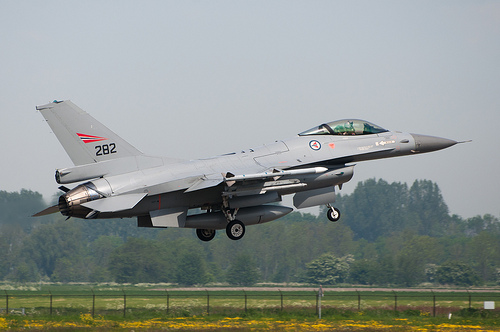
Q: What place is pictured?
A: It is an airport.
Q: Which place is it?
A: It is an airport.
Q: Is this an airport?
A: Yes, it is an airport.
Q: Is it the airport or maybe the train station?
A: It is the airport.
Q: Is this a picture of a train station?
A: No, the picture is showing an airport.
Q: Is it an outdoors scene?
A: Yes, it is outdoors.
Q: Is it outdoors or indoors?
A: It is outdoors.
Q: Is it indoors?
A: No, it is outdoors.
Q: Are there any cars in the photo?
A: No, there are no cars.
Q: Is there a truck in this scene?
A: No, there are no trucks.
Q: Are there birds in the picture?
A: No, there are no birds.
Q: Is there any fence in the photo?
A: Yes, there is a fence.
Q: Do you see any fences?
A: Yes, there is a fence.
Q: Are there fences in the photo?
A: Yes, there is a fence.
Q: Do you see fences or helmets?
A: Yes, there is a fence.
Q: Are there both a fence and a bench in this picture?
A: No, there is a fence but no benches.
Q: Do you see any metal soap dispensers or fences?
A: Yes, there is a metal fence.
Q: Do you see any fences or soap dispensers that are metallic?
A: Yes, the fence is metallic.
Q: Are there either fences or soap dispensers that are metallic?
A: Yes, the fence is metallic.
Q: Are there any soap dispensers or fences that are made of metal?
A: Yes, the fence is made of metal.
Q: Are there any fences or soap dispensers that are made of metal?
A: Yes, the fence is made of metal.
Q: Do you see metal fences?
A: Yes, there is a metal fence.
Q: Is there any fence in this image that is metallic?
A: Yes, there is a fence that is metallic.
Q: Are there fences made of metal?
A: Yes, there is a fence that is made of metal.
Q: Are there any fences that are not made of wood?
A: Yes, there is a fence that is made of metal.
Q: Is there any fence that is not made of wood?
A: Yes, there is a fence that is made of metal.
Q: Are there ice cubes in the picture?
A: No, there are no ice cubes.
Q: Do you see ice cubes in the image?
A: No, there are no ice cubes.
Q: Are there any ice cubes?
A: No, there are no ice cubes.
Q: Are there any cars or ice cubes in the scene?
A: No, there are no ice cubes or cars.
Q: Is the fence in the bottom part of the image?
A: Yes, the fence is in the bottom of the image.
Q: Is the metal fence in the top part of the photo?
A: No, the fence is in the bottom of the image.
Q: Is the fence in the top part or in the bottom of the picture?
A: The fence is in the bottom of the image.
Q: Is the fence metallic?
A: Yes, the fence is metallic.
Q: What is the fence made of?
A: The fence is made of metal.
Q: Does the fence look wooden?
A: No, the fence is metallic.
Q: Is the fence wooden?
A: No, the fence is metallic.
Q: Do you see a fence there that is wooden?
A: No, there is a fence but it is metallic.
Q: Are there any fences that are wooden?
A: No, there is a fence but it is metallic.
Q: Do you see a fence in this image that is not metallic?
A: No, there is a fence but it is metallic.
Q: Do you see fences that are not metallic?
A: No, there is a fence but it is metallic.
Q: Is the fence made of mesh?
A: No, the fence is made of metal.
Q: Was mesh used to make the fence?
A: No, the fence is made of metal.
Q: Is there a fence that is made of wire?
A: No, there is a fence but it is made of metal.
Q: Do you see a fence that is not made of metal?
A: No, there is a fence but it is made of metal.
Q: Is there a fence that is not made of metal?
A: No, there is a fence but it is made of metal.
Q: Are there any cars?
A: No, there are no cars.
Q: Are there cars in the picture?
A: No, there are no cars.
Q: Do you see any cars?
A: No, there are no cars.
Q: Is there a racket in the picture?
A: No, there are no rackets.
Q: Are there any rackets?
A: No, there are no rackets.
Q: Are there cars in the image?
A: No, there are no cars.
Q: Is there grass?
A: Yes, there is grass.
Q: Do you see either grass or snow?
A: Yes, there is grass.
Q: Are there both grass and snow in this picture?
A: No, there is grass but no snow.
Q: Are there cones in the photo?
A: No, there are no cones.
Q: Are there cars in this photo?
A: No, there are no cars.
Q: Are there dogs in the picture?
A: No, there are no dogs.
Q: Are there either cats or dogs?
A: No, there are no dogs or cats.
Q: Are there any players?
A: No, there are no players.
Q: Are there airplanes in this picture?
A: Yes, there is an airplane.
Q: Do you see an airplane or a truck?
A: Yes, there is an airplane.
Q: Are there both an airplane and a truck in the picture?
A: No, there is an airplane but no trucks.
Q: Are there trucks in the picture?
A: No, there are no trucks.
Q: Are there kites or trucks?
A: No, there are no trucks or kites.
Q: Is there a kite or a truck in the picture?
A: No, there are no trucks or kites.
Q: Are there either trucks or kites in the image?
A: No, there are no trucks or kites.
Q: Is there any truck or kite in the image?
A: No, there are no trucks or kites.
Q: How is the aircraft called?
A: The aircraft is an airplane.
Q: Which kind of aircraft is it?
A: The aircraft is an airplane.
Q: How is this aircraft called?
A: This is an airplane.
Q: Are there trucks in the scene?
A: No, there are no trucks.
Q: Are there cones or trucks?
A: No, there are no trucks or cones.